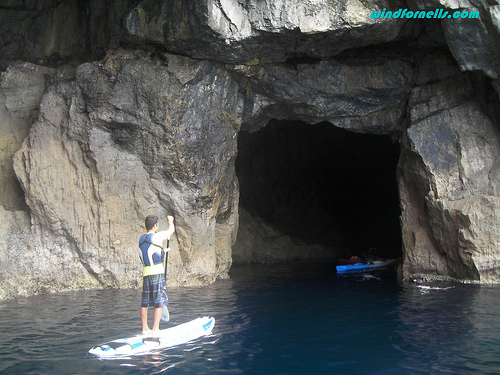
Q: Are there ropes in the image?
A: No, there are no ropes.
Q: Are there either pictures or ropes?
A: No, there are no ropes or pictures.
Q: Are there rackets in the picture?
A: No, there are no rackets.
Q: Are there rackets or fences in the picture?
A: No, there are no rackets or fences.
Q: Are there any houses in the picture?
A: No, there are no houses.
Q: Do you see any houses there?
A: No, there are no houses.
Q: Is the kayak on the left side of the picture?
A: No, the kayak is on the right of the image.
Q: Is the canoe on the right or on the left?
A: The canoe is on the right of the image.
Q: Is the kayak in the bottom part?
A: Yes, the kayak is in the bottom of the image.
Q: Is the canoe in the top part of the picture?
A: No, the canoe is in the bottom of the image.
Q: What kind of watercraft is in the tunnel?
A: The watercraft is a canoe.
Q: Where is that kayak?
A: The kayak is in the tunnel.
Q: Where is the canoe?
A: The kayak is in the tunnel.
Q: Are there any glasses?
A: No, there are no glasses.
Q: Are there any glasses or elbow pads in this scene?
A: No, there are no glasses or elbow pads.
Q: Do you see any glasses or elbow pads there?
A: No, there are no glasses or elbow pads.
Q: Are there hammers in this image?
A: No, there are no hammers.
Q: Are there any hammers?
A: No, there are no hammers.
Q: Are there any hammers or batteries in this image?
A: No, there are no hammers or batteries.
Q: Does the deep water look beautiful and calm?
A: Yes, the water is beautiful and calm.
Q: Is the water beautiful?
A: Yes, the water is beautiful.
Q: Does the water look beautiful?
A: Yes, the water is beautiful.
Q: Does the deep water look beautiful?
A: Yes, the water is beautiful.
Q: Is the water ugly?
A: No, the water is beautiful.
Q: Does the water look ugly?
A: No, the water is beautiful.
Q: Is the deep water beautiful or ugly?
A: The water is beautiful.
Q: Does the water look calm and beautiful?
A: Yes, the water is calm and beautiful.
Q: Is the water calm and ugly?
A: No, the water is calm but beautiful.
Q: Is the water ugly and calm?
A: No, the water is calm but beautiful.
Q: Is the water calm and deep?
A: Yes, the water is calm and deep.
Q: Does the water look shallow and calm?
A: No, the water is calm but deep.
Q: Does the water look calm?
A: Yes, the water is calm.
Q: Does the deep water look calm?
A: Yes, the water is calm.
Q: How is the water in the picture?
A: The water is calm.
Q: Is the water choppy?
A: No, the water is calm.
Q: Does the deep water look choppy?
A: No, the water is calm.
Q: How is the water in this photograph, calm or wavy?
A: The water is calm.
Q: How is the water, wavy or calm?
A: The water is calm.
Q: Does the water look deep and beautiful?
A: Yes, the water is deep and beautiful.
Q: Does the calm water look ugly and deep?
A: No, the water is deep but beautiful.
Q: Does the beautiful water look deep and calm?
A: Yes, the water is deep and calm.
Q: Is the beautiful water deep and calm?
A: Yes, the water is deep and calm.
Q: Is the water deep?
A: Yes, the water is deep.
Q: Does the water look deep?
A: Yes, the water is deep.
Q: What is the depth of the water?
A: The water is deep.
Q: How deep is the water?
A: The water is deep.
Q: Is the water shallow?
A: No, the water is deep.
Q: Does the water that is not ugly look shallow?
A: No, the water is deep.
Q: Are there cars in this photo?
A: No, there are no cars.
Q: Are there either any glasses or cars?
A: No, there are no cars or glasses.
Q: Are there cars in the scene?
A: No, there are no cars.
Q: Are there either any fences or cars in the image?
A: No, there are no cars or fences.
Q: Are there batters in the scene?
A: No, there are no batters.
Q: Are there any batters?
A: No, there are no batters.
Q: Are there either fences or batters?
A: No, there are no batters or fences.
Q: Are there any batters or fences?
A: No, there are no batters or fences.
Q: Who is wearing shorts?
A: The man is wearing shorts.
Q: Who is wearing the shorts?
A: The man is wearing shorts.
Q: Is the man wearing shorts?
A: Yes, the man is wearing shorts.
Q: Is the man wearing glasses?
A: No, the man is wearing shorts.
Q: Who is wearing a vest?
A: The man is wearing a vest.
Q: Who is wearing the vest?
A: The man is wearing a vest.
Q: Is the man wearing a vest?
A: Yes, the man is wearing a vest.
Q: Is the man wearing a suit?
A: No, the man is wearing a vest.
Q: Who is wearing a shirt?
A: The man is wearing a shirt.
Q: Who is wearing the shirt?
A: The man is wearing a shirt.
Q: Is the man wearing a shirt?
A: Yes, the man is wearing a shirt.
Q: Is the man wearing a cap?
A: No, the man is wearing a shirt.